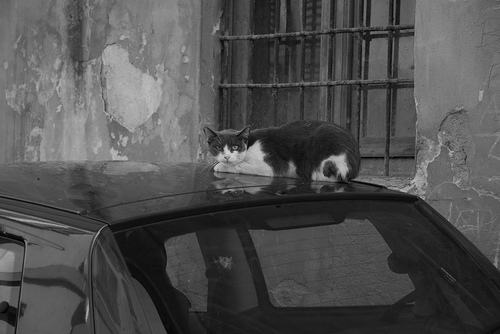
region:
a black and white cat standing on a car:
[208, 105, 355, 185]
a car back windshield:
[290, 225, 440, 315]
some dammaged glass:
[205, 250, 236, 270]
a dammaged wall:
[82, 35, 157, 135]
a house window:
[215, 5, 400, 135]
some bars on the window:
[215, 20, 411, 95]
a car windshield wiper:
[381, 223, 496, 323]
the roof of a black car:
[2, 165, 185, 197]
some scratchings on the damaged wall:
[435, 200, 489, 233]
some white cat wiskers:
[201, 155, 251, 177]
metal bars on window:
[217, 3, 418, 176]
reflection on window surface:
[254, 5, 417, 147]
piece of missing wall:
[433, 103, 480, 189]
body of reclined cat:
[205, 116, 363, 182]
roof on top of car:
[3, 160, 417, 219]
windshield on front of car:
[138, 197, 495, 332]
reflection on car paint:
[1, 208, 128, 332]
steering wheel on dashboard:
[381, 282, 456, 331]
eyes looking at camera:
[210, 142, 240, 154]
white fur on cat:
[213, 139, 274, 176]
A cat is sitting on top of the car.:
[186, 113, 372, 199]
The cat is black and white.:
[181, 116, 386, 209]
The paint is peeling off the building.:
[41, 26, 167, 132]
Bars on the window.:
[202, 23, 435, 171]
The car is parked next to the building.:
[58, 135, 475, 308]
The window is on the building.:
[218, 14, 447, 121]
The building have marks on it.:
[41, 53, 181, 144]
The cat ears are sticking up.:
[193, 114, 257, 173]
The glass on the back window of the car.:
[143, 212, 442, 319]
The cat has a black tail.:
[318, 158, 359, 185]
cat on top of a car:
[202, 117, 359, 202]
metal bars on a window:
[213, 2, 418, 181]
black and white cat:
[208, 117, 353, 178]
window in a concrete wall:
[215, 28, 422, 195]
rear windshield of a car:
[89, 196, 497, 332]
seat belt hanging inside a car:
[202, 263, 227, 321]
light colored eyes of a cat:
[208, 143, 241, 151]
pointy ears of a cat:
[198, 122, 253, 138]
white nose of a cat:
[216, 151, 238, 162]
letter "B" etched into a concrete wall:
[475, 13, 499, 53]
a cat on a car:
[202, 112, 363, 182]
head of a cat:
[203, 124, 250, 164]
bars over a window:
[214, 2, 412, 174]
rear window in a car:
[106, 198, 498, 332]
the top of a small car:
[0, 160, 497, 332]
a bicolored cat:
[201, 118, 360, 183]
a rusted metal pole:
[384, 0, 396, 175]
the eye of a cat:
[230, 141, 238, 151]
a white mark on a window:
[216, 253, 234, 270]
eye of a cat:
[230, 143, 240, 152]